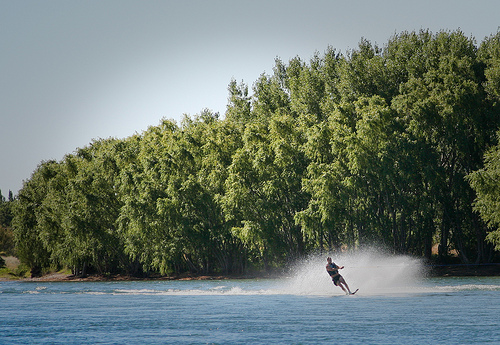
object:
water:
[0, 311, 32, 325]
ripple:
[166, 300, 235, 319]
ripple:
[329, 317, 451, 332]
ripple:
[326, 301, 497, 319]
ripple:
[1, 297, 499, 344]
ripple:
[2, 320, 96, 335]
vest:
[326, 262, 338, 276]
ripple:
[232, 310, 425, 335]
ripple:
[299, 295, 496, 304]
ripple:
[0, 317, 160, 330]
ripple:
[4, 332, 61, 344]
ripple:
[141, 300, 251, 316]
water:
[0, 281, 48, 308]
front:
[351, 287, 360, 296]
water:
[322, 306, 355, 332]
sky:
[39, 47, 100, 108]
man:
[326, 256, 353, 295]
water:
[473, 312, 498, 339]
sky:
[173, 1, 499, 123]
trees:
[280, 55, 312, 268]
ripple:
[212, 282, 274, 302]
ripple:
[112, 309, 372, 328]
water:
[182, 294, 274, 328]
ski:
[350, 288, 359, 294]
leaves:
[251, 120, 292, 175]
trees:
[112, 76, 160, 275]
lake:
[0, 275, 499, 344]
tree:
[383, 25, 475, 263]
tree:
[457, 24, 500, 271]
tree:
[0, 158, 59, 278]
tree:
[82, 134, 112, 278]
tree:
[197, 74, 270, 268]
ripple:
[340, 328, 432, 340]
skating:
[324, 256, 359, 294]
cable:
[343, 261, 499, 268]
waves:
[85, 276, 497, 292]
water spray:
[275, 243, 430, 294]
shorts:
[331, 273, 342, 285]